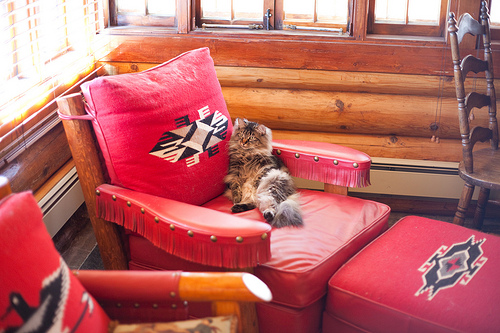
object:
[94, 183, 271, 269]
fringe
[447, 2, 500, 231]
wood chair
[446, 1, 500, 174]
chair back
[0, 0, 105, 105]
window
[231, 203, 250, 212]
cat paw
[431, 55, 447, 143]
string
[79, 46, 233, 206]
cushion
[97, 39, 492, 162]
knoll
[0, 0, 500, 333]
house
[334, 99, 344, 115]
dark spot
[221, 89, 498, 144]
log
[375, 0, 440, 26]
window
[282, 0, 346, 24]
window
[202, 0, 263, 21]
window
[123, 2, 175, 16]
window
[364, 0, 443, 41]
wooden frame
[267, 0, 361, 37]
wooden frame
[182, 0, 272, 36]
wooden frame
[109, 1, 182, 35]
wooden frame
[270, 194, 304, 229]
tail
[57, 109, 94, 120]
strap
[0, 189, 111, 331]
cushion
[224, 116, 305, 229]
cat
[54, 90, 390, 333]
chair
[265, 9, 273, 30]
latch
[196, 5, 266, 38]
windowsill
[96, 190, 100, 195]
nail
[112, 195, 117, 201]
nail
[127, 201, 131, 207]
nail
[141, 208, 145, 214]
nail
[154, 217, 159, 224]
nail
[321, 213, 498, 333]
ottoman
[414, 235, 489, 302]
design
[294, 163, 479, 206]
baseboard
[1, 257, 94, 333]
bird design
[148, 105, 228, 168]
design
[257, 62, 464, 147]
wood